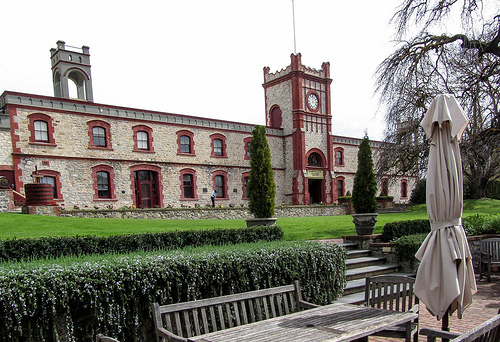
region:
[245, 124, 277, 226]
evergreen tree in planter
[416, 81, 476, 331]
furled outdoor furniture umbrella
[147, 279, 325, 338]
wooden bench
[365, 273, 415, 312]
wooden chair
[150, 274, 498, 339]
rectangular wood table with bench and chair seating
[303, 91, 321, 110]
found clock face with red rim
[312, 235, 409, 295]
stairway from garden level to upper lawn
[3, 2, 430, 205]
large two story European style stone building with clock tower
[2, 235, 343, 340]
hedge pruned to short height and linear shape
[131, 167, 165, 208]
doorway to castle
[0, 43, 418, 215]
beautiful building trimmed in red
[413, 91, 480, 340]
umbrella stored in unused position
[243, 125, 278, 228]
potted plant by a hedge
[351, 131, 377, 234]
potted plant near a hedge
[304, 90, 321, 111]
clock on the tower above the entrance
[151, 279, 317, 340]
wooden bench in front of hedge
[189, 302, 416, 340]
wooden table by an umbrella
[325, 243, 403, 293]
stairs between the hedges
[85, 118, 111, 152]
a window with red rock around it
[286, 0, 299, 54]
a pole on top of the tower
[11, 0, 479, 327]
an estate in the countryside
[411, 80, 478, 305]
an unopened umbrella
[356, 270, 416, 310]
back of a wooden chair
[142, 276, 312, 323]
long bench at a table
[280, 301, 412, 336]
wooden tabletop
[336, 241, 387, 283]
short flight of outdoor stairs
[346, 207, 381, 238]
ornate stone vase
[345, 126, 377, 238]
small evergreen tree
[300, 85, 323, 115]
circular clock face on the facade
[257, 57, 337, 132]
tower in a building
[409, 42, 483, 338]
A closed umbrella in front of a building.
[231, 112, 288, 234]
a tall green bush.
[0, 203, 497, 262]
a long green hedge.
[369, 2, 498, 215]
a tree with lots of branches.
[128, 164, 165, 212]
a window on a building.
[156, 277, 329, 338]
a bench in front of a hedge.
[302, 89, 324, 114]
a clock on the side of a clock tower.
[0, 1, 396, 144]
a hazy gray sky.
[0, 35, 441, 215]
A tan brick building.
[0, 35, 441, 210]
The building has red moldings.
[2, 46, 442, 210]
The building is brick with red trim.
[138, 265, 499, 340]
A sitting area outside.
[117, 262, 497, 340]
A wooden table with chairs.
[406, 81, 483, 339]
A closed tan umbrella next to the table.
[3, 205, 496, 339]
A green hedge next to the table.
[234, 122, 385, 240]
Two small trees in pots.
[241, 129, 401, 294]
Two potted trees by the stairs.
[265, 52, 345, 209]
A clock tower in the center of the building.